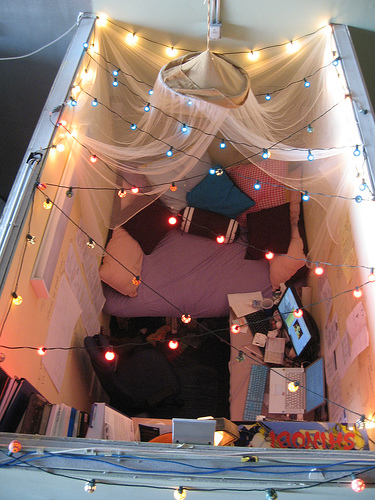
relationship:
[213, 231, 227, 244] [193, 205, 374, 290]
light on cord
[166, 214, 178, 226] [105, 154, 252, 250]
light on cord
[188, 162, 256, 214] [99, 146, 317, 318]
blue pillow on bed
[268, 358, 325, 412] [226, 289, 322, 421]
laptop on desk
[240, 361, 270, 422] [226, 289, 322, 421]
keyboard on desk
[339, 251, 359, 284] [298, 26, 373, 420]
paper to wall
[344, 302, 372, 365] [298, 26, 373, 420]
paper to wall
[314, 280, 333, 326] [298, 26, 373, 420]
paper to wall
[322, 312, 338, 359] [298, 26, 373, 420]
paper to wall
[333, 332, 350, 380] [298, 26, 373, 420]
paper to wall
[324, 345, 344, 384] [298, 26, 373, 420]
paper to wall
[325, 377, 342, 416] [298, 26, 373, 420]
paper to wall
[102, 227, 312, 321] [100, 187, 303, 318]
sheet on bed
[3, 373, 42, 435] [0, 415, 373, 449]
binder on shelf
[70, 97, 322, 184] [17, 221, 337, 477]
mosquito netting over room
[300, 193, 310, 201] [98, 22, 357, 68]
light on string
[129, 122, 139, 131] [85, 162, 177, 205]
light on string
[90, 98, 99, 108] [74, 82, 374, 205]
light on string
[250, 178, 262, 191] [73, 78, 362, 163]
blue light on string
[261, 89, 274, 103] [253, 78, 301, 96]
light on string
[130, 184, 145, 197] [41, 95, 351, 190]
light on string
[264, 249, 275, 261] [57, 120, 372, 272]
light on string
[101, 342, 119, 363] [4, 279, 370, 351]
light on string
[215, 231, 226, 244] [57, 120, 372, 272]
red light on string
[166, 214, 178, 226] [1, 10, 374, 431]
light on string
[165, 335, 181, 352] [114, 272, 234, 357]
light on cord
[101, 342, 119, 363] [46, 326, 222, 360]
light on cord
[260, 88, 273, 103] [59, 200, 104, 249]
light on cord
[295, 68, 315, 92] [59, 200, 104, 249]
light on cord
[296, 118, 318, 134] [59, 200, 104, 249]
light on cord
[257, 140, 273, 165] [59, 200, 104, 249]
light on cord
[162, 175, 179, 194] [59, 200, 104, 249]
light on cord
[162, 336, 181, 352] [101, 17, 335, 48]
light on cord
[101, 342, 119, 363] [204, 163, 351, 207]
light on cord